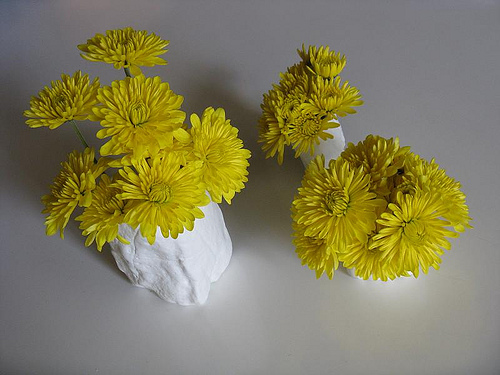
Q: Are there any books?
A: No, there are no books.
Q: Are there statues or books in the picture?
A: No, there are no books or statues.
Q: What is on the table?
A: The flowers are on the table.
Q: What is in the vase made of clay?
A: The flowers are in the vase.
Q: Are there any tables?
A: Yes, there is a table.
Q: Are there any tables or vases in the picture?
A: Yes, there is a table.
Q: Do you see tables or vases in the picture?
A: Yes, there is a table.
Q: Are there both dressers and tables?
A: No, there is a table but no dressers.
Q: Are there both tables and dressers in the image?
A: No, there is a table but no dressers.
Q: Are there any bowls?
A: No, there are no bowls.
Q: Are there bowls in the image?
A: No, there are no bowls.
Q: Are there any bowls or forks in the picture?
A: No, there are no bowls or forks.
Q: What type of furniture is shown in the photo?
A: The furniture is a table.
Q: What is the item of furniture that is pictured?
A: The piece of furniture is a table.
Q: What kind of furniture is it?
A: The piece of furniture is a table.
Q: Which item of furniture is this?
A: This is a table.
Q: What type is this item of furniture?
A: This is a table.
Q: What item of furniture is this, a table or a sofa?
A: This is a table.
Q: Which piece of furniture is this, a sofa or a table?
A: This is a table.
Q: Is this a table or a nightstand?
A: This is a table.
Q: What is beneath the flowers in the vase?
A: The table is beneath the flowers.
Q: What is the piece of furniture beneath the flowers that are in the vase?
A: The piece of furniture is a table.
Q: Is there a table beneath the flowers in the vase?
A: Yes, there is a table beneath the flowers.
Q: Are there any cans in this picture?
A: No, there are no cans.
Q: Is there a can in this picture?
A: No, there are no cans.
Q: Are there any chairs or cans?
A: No, there are no cans or chairs.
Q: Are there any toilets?
A: No, there are no toilets.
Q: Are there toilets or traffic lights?
A: No, there are no toilets or traffic lights.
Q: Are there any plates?
A: No, there are no plates.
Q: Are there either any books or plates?
A: No, there are no plates or books.